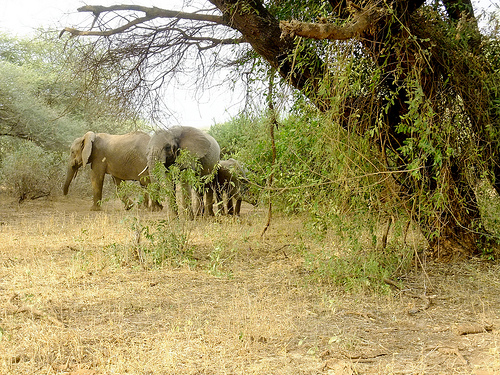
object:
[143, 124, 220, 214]
elephant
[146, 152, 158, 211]
trunk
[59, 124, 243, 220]
elephants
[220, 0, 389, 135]
branch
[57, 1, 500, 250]
tree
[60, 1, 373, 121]
branches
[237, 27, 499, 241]
leaves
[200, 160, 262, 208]
elephant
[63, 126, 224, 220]
elephants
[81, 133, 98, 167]
ear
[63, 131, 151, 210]
elephant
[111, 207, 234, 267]
stick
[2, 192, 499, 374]
ground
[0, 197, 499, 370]
grass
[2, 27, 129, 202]
tree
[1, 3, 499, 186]
background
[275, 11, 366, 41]
branch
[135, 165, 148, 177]
tusk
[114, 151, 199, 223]
shrub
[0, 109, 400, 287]
shrubs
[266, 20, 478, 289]
vines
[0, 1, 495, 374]
forest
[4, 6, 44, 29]
sky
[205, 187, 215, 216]
trunk